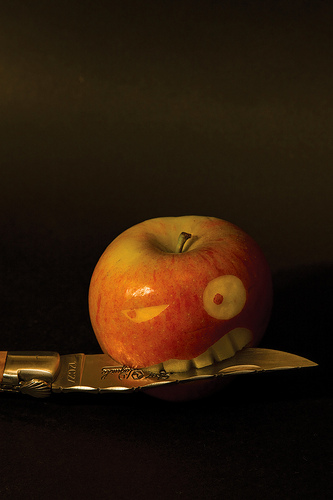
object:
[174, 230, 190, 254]
stem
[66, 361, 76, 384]
number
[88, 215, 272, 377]
apple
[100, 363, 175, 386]
carvings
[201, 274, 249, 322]
eye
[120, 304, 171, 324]
eyes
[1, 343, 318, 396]
pocket knife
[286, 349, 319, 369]
knife point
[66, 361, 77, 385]
writing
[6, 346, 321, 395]
blade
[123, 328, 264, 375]
teeth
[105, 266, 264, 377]
face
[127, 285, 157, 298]
light reflection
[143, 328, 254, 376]
bad sentence